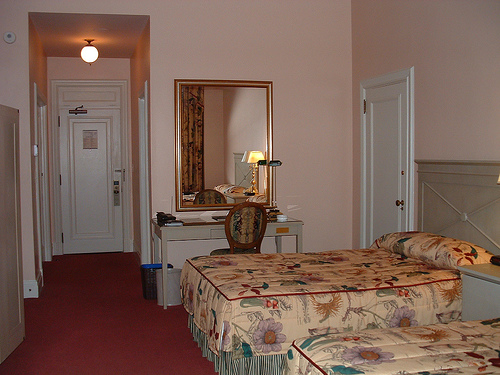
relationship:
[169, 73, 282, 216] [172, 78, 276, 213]
mirror has frame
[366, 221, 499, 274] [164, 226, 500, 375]
pillow on bed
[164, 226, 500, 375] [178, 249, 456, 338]
bed has blanket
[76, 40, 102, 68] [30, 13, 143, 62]
light hangs from ceiling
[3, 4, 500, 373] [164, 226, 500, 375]
room has two beds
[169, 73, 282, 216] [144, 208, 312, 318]
mirror above desk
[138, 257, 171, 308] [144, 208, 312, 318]
garbage can under desk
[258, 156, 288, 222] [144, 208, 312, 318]
desk lamp sitting on desk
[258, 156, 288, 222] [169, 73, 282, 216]
desk lamp reflects in mirror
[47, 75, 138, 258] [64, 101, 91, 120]
mechanical door has closer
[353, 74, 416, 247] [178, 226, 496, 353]
door beside bed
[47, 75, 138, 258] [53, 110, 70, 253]
door with gold hinges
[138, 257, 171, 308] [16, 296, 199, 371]
garbage can on floor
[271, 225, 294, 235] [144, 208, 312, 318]
marking on table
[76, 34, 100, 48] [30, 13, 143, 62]
light fixture mounted in ceiling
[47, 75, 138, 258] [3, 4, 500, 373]
exit door of apartment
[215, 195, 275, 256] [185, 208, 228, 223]
chair used for cosmetics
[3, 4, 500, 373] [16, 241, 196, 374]
room has red carpet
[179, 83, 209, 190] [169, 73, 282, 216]
drapes reflection in mirror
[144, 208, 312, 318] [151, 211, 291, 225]
table for personal items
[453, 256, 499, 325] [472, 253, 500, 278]
nightstand for personal items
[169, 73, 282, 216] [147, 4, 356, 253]
mirror on wall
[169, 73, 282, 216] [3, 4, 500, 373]
mirror reflects room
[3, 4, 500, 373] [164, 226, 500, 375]
hotel room has two beds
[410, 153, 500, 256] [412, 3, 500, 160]
headboard on wall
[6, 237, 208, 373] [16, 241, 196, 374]
carpet on floor